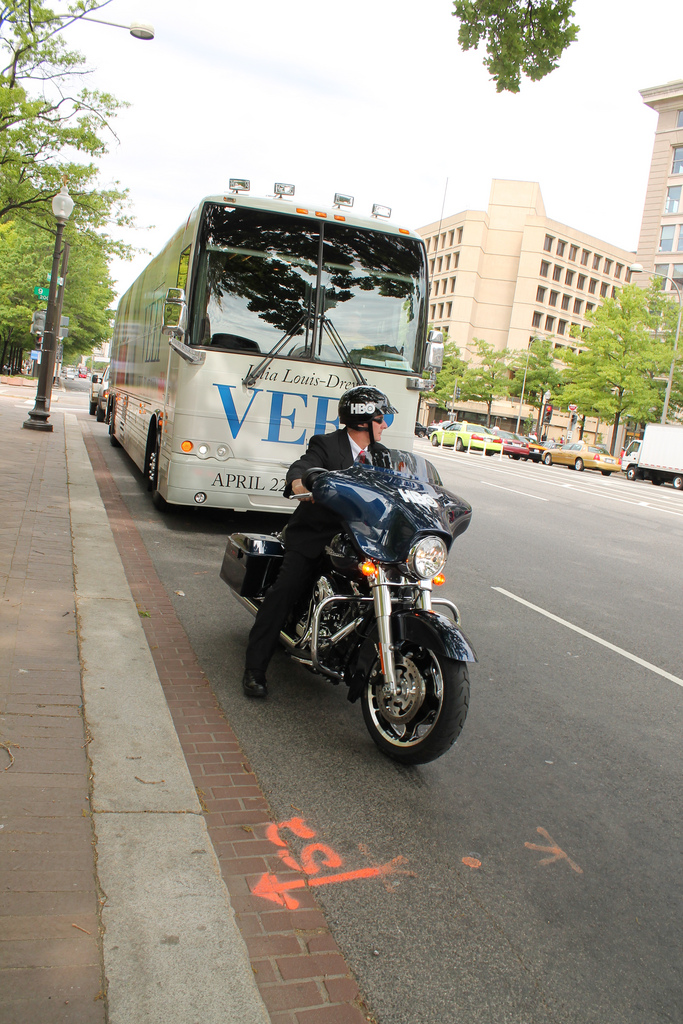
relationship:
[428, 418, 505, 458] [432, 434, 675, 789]
car on street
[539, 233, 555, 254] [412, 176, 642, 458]
window on building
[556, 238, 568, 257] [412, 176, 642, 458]
window on building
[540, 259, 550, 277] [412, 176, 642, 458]
window on building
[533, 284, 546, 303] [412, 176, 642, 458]
window on building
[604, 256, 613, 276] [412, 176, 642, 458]
window on building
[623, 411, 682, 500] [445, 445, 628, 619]
truck on street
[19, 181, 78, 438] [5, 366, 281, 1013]
lampost on sidewalk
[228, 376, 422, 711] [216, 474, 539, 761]
man on motorcycle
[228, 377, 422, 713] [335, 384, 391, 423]
man wearing helmet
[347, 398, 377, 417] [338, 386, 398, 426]
hbo on helmet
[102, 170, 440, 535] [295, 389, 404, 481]
bus behind man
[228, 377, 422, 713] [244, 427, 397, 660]
man wears suit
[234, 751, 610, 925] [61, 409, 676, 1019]
writing on street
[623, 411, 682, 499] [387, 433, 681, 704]
truck on road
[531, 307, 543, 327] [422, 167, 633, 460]
window has building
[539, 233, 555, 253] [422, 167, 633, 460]
window on building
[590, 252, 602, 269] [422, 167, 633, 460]
window on building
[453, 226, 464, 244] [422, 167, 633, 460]
window on building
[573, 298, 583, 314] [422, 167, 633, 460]
window on building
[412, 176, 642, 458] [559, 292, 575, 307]
building has window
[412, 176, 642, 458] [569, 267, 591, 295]
building has window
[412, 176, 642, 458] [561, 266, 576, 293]
building has window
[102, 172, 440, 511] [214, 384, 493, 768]
bus behind motorcyclist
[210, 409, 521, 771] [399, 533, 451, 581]
motorcycle has headlight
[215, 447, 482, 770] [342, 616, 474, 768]
motorcycle has wheel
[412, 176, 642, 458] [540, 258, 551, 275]
building with window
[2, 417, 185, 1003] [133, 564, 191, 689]
sidewalk from brick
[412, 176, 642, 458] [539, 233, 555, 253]
building has window